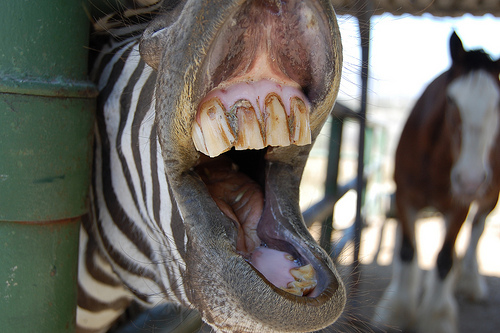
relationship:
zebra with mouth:
[78, 0, 347, 331] [174, 27, 313, 297]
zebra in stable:
[78, 0, 354, 331] [0, 0, 499, 332]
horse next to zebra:
[366, 24, 499, 331] [78, 0, 354, 331]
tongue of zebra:
[219, 185, 260, 237] [93, 12, 238, 312]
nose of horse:
[456, 175, 491, 193] [366, 24, 499, 331]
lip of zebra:
[188, 226, 376, 328] [102, 54, 393, 314]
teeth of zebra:
[188, 89, 316, 154] [78, 0, 354, 331]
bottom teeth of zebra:
[286, 253, 324, 303] [78, 0, 354, 331]